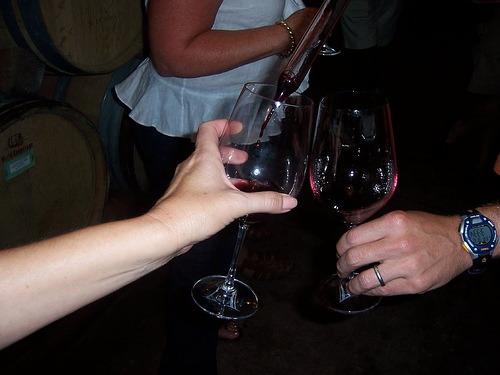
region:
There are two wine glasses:
[199, 68, 404, 316]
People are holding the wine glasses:
[1, 82, 493, 345]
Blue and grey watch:
[448, 205, 498, 285]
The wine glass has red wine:
[311, 85, 403, 317]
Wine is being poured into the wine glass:
[181, 13, 343, 320]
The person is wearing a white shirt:
[123, 10, 326, 145]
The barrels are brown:
[13, 17, 139, 248]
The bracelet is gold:
[272, 16, 299, 73]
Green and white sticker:
[6, 144, 43, 190]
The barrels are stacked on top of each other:
[15, 13, 155, 246]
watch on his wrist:
[447, 200, 496, 282]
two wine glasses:
[239, 103, 408, 202]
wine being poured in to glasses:
[235, 43, 316, 139]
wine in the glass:
[218, 170, 271, 194]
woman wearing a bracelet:
[257, 4, 306, 65]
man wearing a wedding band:
[357, 267, 396, 293]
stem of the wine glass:
[181, 228, 266, 326]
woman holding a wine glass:
[185, 118, 298, 244]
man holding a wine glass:
[325, 111, 418, 329]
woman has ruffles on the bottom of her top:
[119, 77, 202, 127]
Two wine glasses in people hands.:
[193, 75, 421, 330]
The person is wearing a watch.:
[433, 182, 495, 279]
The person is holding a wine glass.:
[155, 107, 277, 321]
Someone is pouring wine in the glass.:
[265, 8, 356, 104]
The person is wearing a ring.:
[366, 257, 388, 290]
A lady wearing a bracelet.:
[268, 16, 305, 60]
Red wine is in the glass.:
[326, 126, 405, 228]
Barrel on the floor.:
[15, 101, 115, 216]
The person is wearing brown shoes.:
[251, 241, 304, 285]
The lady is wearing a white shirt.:
[138, 28, 273, 130]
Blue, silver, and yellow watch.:
[437, 202, 498, 282]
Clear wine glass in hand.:
[185, 66, 313, 328]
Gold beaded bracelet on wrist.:
[269, 13, 296, 56]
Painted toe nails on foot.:
[217, 317, 242, 341]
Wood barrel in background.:
[1, 88, 111, 252]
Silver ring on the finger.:
[340, 233, 418, 303]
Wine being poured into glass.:
[253, 3, 342, 160]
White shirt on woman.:
[129, 0, 313, 205]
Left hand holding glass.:
[327, 194, 495, 299]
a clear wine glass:
[187, 79, 315, 321]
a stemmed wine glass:
[308, 92, 400, 315]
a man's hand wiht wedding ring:
[334, 202, 496, 298]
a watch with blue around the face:
[461, 210, 498, 266]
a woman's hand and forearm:
[0, 116, 300, 348]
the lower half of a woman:
[110, 0, 325, 216]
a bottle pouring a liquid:
[275, 0, 340, 113]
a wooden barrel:
[0, 83, 113, 252]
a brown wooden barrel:
[1, 0, 151, 81]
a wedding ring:
[372, 263, 387, 287]